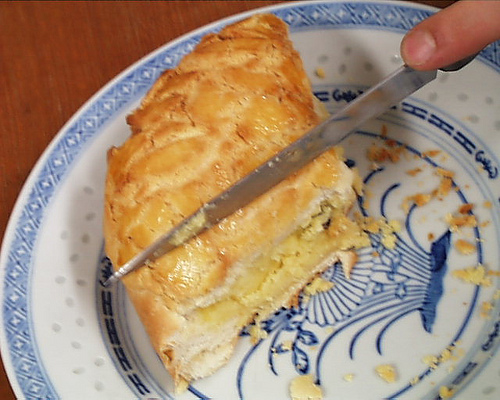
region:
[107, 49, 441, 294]
a silver sharp knife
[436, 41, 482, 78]
a handle of a knife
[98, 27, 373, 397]
a piece of pie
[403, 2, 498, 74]
a finger holding a knife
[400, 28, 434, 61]
a pink round fingernail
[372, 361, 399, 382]
a tiny crumb of pie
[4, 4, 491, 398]
a decorative blue and white plate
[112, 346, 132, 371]
a blue letter H on plate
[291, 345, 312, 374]
a drawing of a leaf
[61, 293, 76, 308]
a gray spot on plate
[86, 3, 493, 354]
a person is cutting the cake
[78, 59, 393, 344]
the cake is moist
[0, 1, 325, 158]
the table is brown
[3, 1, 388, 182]
the table is made of wood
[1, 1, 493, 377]
the plate is round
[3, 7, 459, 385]
the plate is blue and white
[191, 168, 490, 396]
the plate has a picture of vase on the middle of it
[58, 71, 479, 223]
the knife is silver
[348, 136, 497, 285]
crumbs are on the plate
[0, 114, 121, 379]
diamonds are all around the edge of plate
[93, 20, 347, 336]
brown food on table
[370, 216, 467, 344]
blue art on table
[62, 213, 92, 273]
white plate with food on it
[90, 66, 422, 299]
silver knife cutting cake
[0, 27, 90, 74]
brown table under plate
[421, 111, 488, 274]
white and blue plate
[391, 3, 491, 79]
finger on a knife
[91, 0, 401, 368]
brown piece of cake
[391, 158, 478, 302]
crumbs on the plate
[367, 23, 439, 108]
fingernail of person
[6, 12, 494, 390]
blue and white plate with pastry on top of it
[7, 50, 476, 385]
blue and white plate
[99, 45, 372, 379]
pastry on top of blue and white plate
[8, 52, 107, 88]
wooden table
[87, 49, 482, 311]
knife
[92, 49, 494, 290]
knife cutting pastry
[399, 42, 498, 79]
finger of hand cutting pastry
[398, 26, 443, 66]
fingernail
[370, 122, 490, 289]
crumbs of pastry laying on blue and white plate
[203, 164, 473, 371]
emblem on the blue and white plate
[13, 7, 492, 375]
Blue and White plate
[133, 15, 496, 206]
Person slicing a piece of pie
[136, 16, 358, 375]
Pie on top a place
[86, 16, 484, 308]
Person holding knife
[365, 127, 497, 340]
Crumbs on top of plate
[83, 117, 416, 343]
Knife cutting into pie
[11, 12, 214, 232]
Plate on a brown table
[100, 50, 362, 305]
Golden Brown pie crust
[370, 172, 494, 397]
Blue and white plate design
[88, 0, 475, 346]
Person cutting a piece of pie